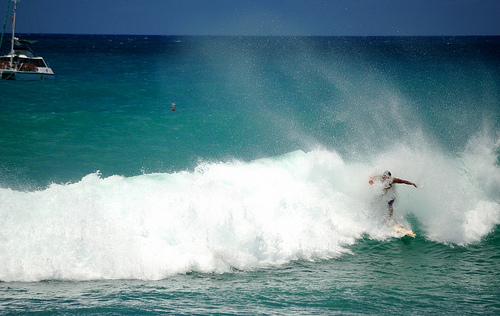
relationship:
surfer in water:
[346, 148, 423, 248] [280, 266, 376, 312]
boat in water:
[0, 19, 76, 91] [280, 266, 376, 312]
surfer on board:
[346, 148, 423, 248] [390, 222, 415, 246]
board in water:
[390, 222, 415, 246] [280, 266, 376, 312]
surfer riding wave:
[346, 148, 423, 248] [222, 156, 285, 248]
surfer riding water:
[346, 148, 423, 248] [280, 266, 376, 312]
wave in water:
[222, 156, 285, 248] [280, 266, 376, 312]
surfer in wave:
[346, 148, 423, 248] [222, 156, 285, 248]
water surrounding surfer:
[280, 266, 376, 312] [346, 148, 423, 248]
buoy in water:
[159, 99, 184, 116] [280, 266, 376, 312]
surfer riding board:
[346, 148, 423, 248] [390, 222, 415, 246]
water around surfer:
[280, 266, 376, 312] [346, 148, 423, 248]